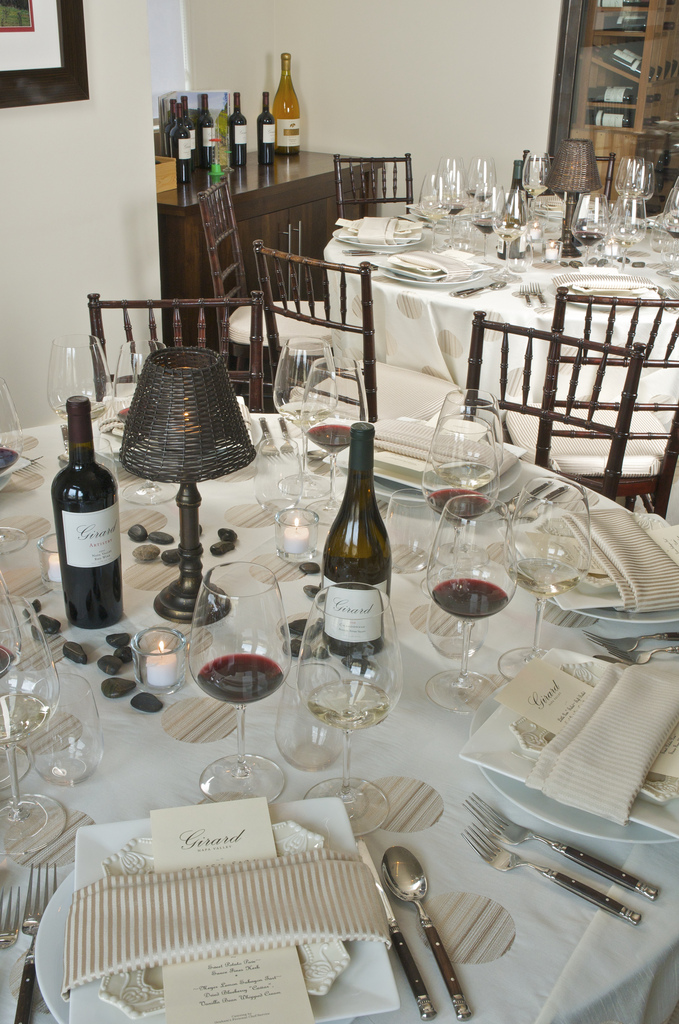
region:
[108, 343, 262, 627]
Black wicker lampshade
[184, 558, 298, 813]
Wine glass with red wine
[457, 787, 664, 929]
Two forks next to each other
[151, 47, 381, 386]
wine bottles on a counter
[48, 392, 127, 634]
Unopened wine bottle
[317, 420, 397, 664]
Unopened green wine bottle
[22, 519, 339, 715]
Black small stones on the table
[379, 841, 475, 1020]
Spoon with brown hand grip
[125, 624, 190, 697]
Lighted candle on a glass holder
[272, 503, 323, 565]
Lighted candle on a glass holder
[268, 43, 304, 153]
Bottle of white wine on counter top.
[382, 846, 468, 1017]
Spoon sitting on top of table.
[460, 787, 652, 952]
2 forks sitting on top of table.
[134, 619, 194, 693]
Small white candle sitting on table.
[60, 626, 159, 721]
Smooth black rocks sitting on table.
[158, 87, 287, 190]
Bottles of wine on wood stand.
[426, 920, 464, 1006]
Wood handle on spoon.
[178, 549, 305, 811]
A little wine in a glass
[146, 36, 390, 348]
Many bottles on a brown table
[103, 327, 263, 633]
A brown lamp on a table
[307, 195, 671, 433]
White tablecloth on the table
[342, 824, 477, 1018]
A knife and a spoon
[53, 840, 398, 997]
A folded striped napkin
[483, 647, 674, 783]
A rectangular white menu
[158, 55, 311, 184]
Wine bottle at the corner.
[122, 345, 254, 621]
The lampshade on table.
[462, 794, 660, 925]
The eating forks on the table.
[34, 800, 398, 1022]
A guest invitation on the plate.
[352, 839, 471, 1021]
The eating spoon and knife.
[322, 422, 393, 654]
The wine bottle on the right.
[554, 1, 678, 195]
The wine rack at the corner.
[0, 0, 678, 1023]
A wine sampling restaurant.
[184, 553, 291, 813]
wine glass on the white table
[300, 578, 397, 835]
wine glass on the white table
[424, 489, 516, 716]
wine glass on the white table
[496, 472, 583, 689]
wine glass on the white table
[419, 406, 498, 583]
wine glass on the white table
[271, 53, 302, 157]
A tall yellow tinted bottle.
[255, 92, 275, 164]
Black bottle of wine with white label next to a yellow one.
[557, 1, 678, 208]
Many shelves with angled bottles of wine past the glass.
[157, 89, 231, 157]
Opened book behind all the wine.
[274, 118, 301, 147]
White label on the giant yellow wine bottle.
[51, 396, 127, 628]
Large black bottle of wine next to a grey lamp.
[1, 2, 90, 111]
A dark framed picture on the wall.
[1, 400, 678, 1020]
A white topped table that is closest.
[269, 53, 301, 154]
Giant yellow bottle of wine.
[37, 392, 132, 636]
The wine is on the table.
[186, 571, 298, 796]
A glass of red is poured.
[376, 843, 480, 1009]
A spoon is on the table.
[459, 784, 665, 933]
Two forks are next to each other.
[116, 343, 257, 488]
A candle is on the table.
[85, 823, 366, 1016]
An invitation is on the plate.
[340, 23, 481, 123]
The wall is white.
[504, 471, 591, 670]
The wine is white.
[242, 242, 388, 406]
The chair is wooden.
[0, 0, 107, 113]
The painting is on the wall.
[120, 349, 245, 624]
a lamp on a table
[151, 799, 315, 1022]
a name card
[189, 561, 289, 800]
a glass with red wine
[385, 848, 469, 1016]
a spoon on a table